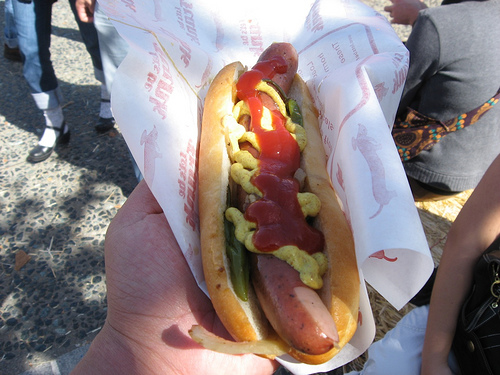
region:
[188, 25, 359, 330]
a part of food item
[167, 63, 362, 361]
a part of hot item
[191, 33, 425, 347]
a part of sweet food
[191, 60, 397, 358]
a part of hot food item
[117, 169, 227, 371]
hand of the boy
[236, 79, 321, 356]
decorations on the food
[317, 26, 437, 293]
a cover in the hand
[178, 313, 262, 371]
a piece of food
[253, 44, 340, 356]
hot dog in bun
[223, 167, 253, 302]
green pickle in bun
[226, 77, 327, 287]
mustard on hot dog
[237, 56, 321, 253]
ketchup on hot dog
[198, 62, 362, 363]
hot dog bun in paper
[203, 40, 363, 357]
dressed hot dog in bun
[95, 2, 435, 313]
food paper in hand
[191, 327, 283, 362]
white onion in bun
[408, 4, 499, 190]
grey cotton sweater jacket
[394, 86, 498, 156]
multi colored cross over bag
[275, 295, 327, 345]
a hot dog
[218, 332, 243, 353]
a white onion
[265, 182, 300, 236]
ketsup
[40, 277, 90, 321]
a shadow on the ground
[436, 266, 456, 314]
a persons arm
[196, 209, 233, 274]
the bun on the hotdog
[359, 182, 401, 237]
the paper is white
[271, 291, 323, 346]
a hot dog on the bun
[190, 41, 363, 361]
Hotdog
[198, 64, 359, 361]
Hotdog bun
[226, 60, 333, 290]
Ketchup and mustard on the hotdog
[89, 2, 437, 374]
Paper wrap used to hold the hotdog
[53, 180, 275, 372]
Hand holding the hot dog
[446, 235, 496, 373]
Black purse around the lady's lap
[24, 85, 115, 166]
Pair of shoes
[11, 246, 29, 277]
Leaf on the ground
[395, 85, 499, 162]
Handbag wrapped around the person's body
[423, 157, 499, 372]
Arm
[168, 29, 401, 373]
a long hot dog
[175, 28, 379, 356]
a long bun for hotdog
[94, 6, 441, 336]
a white paper around hotdog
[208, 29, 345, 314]
ketchup and mustard on hotdog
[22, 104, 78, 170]
a black shoe with strap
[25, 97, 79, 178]
white socks in a black shoe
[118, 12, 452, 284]
a red and white paper under hotdog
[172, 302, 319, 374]
an onion coming out from hot dog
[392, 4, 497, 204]
a medium gray sweater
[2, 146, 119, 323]
black spots on the ground